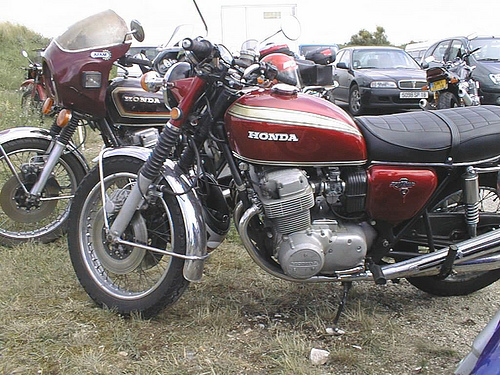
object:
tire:
[64, 154, 191, 319]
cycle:
[418, 45, 487, 111]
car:
[419, 34, 500, 105]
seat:
[354, 101, 500, 166]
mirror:
[279, 10, 302, 42]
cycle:
[0, 8, 176, 249]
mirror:
[129, 19, 144, 42]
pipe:
[364, 225, 500, 281]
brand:
[246, 128, 298, 142]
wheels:
[61, 152, 191, 319]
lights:
[55, 108, 72, 127]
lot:
[0, 8, 500, 330]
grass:
[0, 16, 500, 375]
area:
[0, 14, 498, 369]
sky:
[0, 0, 497, 56]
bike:
[65, 35, 497, 333]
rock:
[308, 346, 329, 369]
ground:
[0, 20, 498, 371]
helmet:
[258, 51, 302, 93]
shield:
[259, 52, 301, 88]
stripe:
[229, 100, 364, 136]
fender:
[90, 146, 208, 282]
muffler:
[334, 223, 500, 283]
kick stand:
[326, 282, 353, 333]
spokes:
[73, 171, 174, 302]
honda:
[246, 129, 300, 143]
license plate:
[400, 91, 429, 98]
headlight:
[369, 80, 398, 90]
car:
[330, 45, 428, 116]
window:
[351, 48, 421, 69]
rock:
[326, 326, 334, 336]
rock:
[243, 327, 251, 336]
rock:
[272, 313, 282, 320]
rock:
[258, 323, 264, 330]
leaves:
[344, 26, 393, 48]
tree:
[334, 25, 412, 58]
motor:
[258, 168, 375, 280]